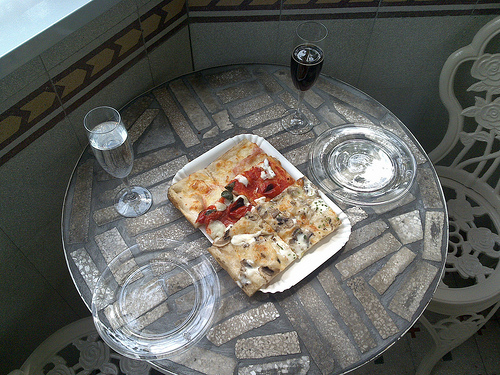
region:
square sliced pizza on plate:
[165, 126, 343, 305]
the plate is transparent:
[88, 227, 232, 374]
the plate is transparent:
[285, 106, 450, 258]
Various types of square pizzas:
[182, 146, 334, 276]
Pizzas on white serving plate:
[182, 145, 337, 290]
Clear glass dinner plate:
[94, 240, 216, 361]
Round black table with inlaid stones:
[334, 240, 448, 364]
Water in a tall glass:
[82, 106, 140, 226]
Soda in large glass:
[275, 19, 332, 133]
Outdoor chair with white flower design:
[447, 53, 494, 309]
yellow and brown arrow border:
[80, 14, 165, 85]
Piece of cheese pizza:
[172, 171, 216, 215]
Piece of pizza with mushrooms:
[214, 230, 238, 250]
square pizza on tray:
[155, 131, 325, 287]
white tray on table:
[179, 125, 313, 295]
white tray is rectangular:
[147, 155, 344, 291]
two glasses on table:
[108, 20, 341, 265]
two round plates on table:
[100, 124, 402, 359]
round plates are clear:
[347, 98, 426, 205]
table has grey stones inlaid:
[40, 138, 447, 300]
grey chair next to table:
[419, 46, 497, 330]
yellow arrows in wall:
[22, 21, 177, 142]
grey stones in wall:
[176, 21, 277, 72]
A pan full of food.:
[164, 125, 355, 298]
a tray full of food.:
[159, 125, 371, 297]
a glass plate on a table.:
[84, 233, 239, 361]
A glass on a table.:
[75, 100, 172, 220]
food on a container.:
[173, 155, 283, 220]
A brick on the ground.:
[353, 239, 423, 303]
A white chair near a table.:
[409, 22, 497, 354]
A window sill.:
[0, 0, 95, 60]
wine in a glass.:
[289, 31, 329, 103]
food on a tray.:
[199, 206, 320, 294]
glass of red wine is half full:
[281, 15, 327, 135]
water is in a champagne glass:
[82, 103, 156, 218]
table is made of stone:
[60, 57, 452, 369]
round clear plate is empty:
[91, 238, 221, 362]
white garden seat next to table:
[429, 10, 498, 374]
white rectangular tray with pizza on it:
[166, 130, 349, 299]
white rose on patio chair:
[461, 94, 498, 133]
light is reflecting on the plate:
[313, 120, 417, 208]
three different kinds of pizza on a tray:
[167, 140, 341, 292]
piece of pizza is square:
[203, 207, 297, 297]